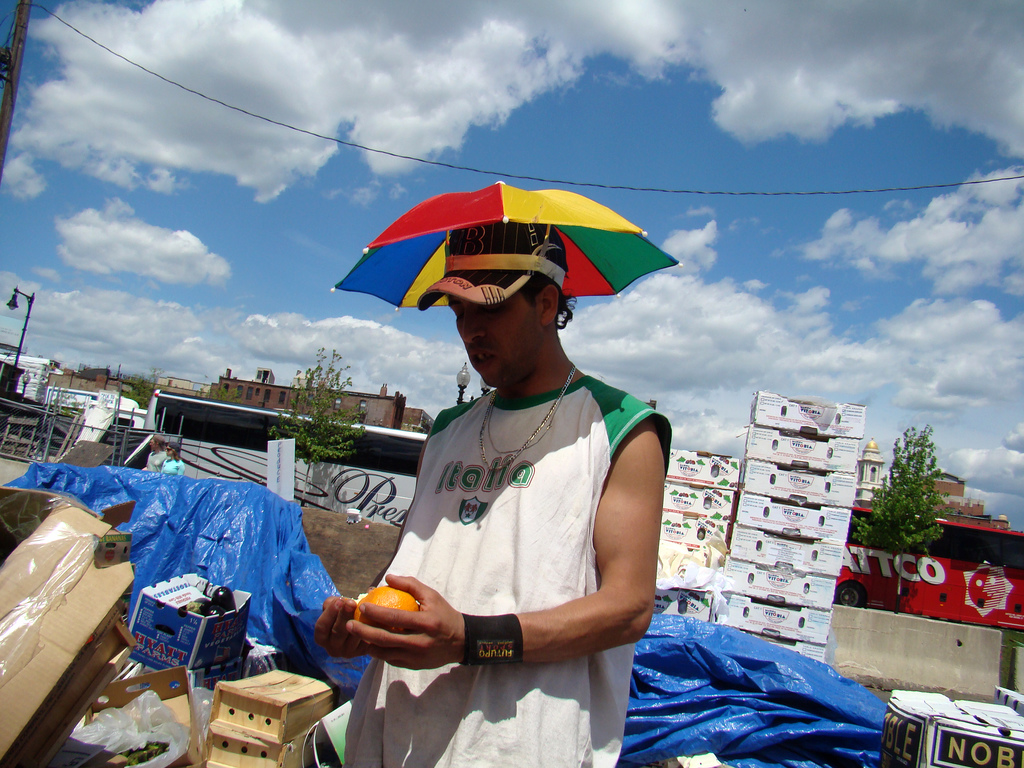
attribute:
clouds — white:
[3, 1, 1023, 524]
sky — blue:
[7, 3, 1023, 529]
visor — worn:
[322, 175, 685, 325]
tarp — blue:
[47, 446, 343, 676]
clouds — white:
[52, 35, 366, 191]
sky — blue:
[32, 22, 1022, 256]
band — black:
[448, 599, 528, 680]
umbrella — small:
[335, 169, 677, 299]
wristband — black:
[451, 605, 544, 675]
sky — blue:
[782, 240, 1020, 437]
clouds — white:
[883, 325, 927, 377]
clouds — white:
[663, 273, 726, 340]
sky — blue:
[600, 199, 771, 366]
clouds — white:
[671, 329, 756, 388]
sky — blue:
[645, 269, 764, 425]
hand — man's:
[350, 575, 472, 664]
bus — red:
[860, 508, 1020, 604]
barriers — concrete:
[842, 597, 1005, 708]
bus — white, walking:
[153, 385, 439, 515]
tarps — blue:
[49, 452, 909, 761]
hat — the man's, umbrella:
[327, 178, 684, 326]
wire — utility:
[31, 5, 991, 204]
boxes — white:
[691, 446, 843, 594]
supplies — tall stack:
[723, 385, 870, 669]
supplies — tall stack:
[662, 444, 743, 594]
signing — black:
[876, 707, 926, 759]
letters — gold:
[870, 705, 914, 745]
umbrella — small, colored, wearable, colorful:
[325, 175, 680, 318]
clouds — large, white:
[57, 9, 501, 178]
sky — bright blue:
[3, 1, 993, 384]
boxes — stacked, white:
[677, 385, 870, 664]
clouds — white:
[49, 204, 235, 300]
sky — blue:
[462, 48, 959, 230]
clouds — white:
[658, 249, 957, 381]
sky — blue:
[200, 178, 348, 285]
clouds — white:
[675, 305, 961, 396]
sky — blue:
[550, 93, 730, 204]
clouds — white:
[38, 3, 663, 151]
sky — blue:
[53, 9, 972, 360]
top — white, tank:
[336, 368, 667, 764]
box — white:
[870, 665, 1022, 761]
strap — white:
[423, 243, 598, 295]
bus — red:
[835, 501, 1023, 627]